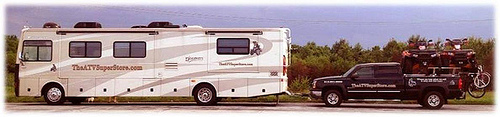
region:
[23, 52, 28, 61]
A side mirror on a bus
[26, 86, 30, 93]
A black spot on the bus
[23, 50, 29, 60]
The driver in the bus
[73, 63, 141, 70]
Words on the bus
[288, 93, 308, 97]
A tow bar between the vehicles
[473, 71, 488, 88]
A bicycle wheel in the back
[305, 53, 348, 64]
A forest along the road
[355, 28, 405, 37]
The sky above the fores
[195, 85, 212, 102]
The rear wheel of the bus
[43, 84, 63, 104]
The bus front wheel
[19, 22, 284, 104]
An RV on the road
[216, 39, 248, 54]
A window on the RV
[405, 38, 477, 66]
ATVs on the truck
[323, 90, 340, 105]
A front wheel on the truck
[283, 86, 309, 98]
A connector between the RV and the truck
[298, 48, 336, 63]
Trees to the side of the RV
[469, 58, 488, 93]
Bicycles behind the truck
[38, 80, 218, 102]
The wheels of the RV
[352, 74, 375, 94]
A door on the truck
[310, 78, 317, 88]
The front lights on the truck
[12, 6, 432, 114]
an rv pulling a truck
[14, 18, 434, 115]
an rv towing a truck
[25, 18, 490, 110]
an rv pulling a black truck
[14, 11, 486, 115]
an rv towing a black truck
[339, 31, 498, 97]
a black truck with four wheelers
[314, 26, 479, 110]
four wheelers on the back of a truck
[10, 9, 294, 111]
an rv on the road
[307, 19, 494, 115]
a black truck on the road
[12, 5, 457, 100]
an rv pulling a truck on the road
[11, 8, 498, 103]
an rv and truck on the road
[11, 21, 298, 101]
large recreational vehicle on the road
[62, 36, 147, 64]
two windows on the side of the RV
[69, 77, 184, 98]
row of five black squares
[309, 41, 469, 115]
black truck on the road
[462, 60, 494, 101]
bike on the back of the truck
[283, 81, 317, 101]
chain connecting the truck to the RV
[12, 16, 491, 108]
RV towing a truck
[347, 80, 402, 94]
writing on the side of the truck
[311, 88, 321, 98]
silver bumper on the side of the bus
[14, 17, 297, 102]
tan and white bus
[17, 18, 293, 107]
White super long camper.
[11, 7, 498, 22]
Blue gray sky with no clouds visible.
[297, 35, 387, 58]
Tall trees in a forest.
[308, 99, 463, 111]
The dark shadow of a big truck.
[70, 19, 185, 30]
Sky lights and heat holes on travelling van.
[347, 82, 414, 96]
White geometric design on the side of a black truck.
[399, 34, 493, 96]
Motor bikes on the back of a truck.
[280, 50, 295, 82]
Red tailights glowing in the day time.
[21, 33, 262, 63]
Four windows trimmed in black.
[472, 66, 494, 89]
Silver wheels shinning in the suns.